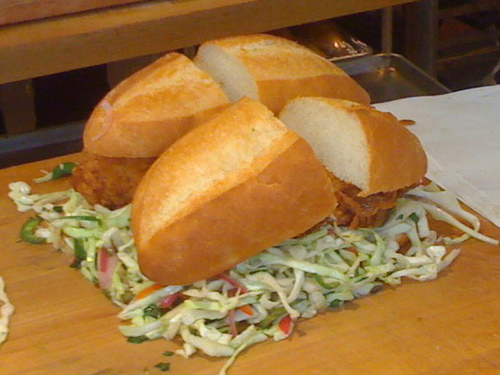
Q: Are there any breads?
A: Yes, there is a bread.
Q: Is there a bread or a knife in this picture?
A: Yes, there is a bread.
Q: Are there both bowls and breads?
A: No, there is a bread but no bowls.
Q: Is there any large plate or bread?
A: Yes, there is a large bread.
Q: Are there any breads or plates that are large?
A: Yes, the bread is large.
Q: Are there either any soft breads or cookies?
A: Yes, there is a soft bread.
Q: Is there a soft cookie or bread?
A: Yes, there is a soft bread.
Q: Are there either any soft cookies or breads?
A: Yes, there is a soft bread.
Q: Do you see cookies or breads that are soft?
A: Yes, the bread is soft.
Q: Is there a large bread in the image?
A: Yes, there is a large bread.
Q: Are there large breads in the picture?
A: Yes, there is a large bread.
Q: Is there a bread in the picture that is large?
A: Yes, there is a bread that is large.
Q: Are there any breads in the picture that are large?
A: Yes, there is a bread that is large.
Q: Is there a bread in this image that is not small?
A: Yes, there is a large bread.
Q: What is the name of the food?
A: The food is a bread.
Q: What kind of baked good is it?
A: The food is a bread.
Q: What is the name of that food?
A: This is a bread.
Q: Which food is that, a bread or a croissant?
A: This is a bread.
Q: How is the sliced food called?
A: The food is a bread.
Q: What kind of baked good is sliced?
A: The baked good is a bread.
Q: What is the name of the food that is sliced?
A: The food is a bread.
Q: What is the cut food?
A: The food is a bread.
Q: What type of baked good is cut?
A: The baked good is a bread.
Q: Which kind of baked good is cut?
A: The baked good is a bread.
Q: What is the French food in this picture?
A: The food is a bread.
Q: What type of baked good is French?
A: The baked good is a bread.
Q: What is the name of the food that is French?
A: The food is a bread.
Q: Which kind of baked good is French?
A: The baked good is a bread.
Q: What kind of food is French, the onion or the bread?
A: The bread is french.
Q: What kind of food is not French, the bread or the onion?
A: The onion is not french.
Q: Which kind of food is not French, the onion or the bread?
A: The onion is not french.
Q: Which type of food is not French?
A: The food is an onion.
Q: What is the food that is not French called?
A: The food is an onion.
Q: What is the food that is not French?
A: The food is an onion.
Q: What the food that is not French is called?
A: The food is an onion.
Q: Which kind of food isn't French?
A: The food is an onion.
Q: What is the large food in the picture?
A: The food is a bread.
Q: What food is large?
A: The food is a bread.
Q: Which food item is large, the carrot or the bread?
A: The bread is large.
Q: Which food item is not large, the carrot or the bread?
A: The carrot is not large.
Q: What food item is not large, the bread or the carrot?
A: The carrot is not large.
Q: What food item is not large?
A: The food item is a carrot.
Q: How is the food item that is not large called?
A: The food item is a carrot.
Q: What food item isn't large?
A: The food item is a carrot.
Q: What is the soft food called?
A: The food is a bread.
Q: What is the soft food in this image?
A: The food is a bread.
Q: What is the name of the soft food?
A: The food is a bread.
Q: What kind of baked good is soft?
A: The baked good is a bread.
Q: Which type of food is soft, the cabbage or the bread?
A: The bread is soft.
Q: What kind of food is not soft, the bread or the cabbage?
A: The cabbage is not soft.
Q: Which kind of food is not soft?
A: The food is a cabbage.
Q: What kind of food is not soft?
A: The food is a cabbage.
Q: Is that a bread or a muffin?
A: That is a bread.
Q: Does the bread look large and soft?
A: Yes, the bread is large and soft.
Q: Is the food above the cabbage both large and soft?
A: Yes, the bread is large and soft.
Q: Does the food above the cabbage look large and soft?
A: Yes, the bread is large and soft.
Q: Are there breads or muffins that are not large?
A: No, there is a bread but it is large.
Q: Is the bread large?
A: Yes, the bread is large.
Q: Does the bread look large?
A: Yes, the bread is large.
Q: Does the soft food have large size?
A: Yes, the bread is large.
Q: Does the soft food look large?
A: Yes, the bread is large.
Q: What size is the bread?
A: The bread is large.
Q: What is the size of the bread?
A: The bread is large.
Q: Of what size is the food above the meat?
A: The bread is large.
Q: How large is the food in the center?
A: The bread is large.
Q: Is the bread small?
A: No, the bread is large.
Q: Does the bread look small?
A: No, the bread is large.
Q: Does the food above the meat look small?
A: No, the bread is large.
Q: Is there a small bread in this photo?
A: No, there is a bread but it is large.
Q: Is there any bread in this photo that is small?
A: No, there is a bread but it is large.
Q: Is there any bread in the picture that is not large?
A: No, there is a bread but it is large.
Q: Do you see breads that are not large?
A: No, there is a bread but it is large.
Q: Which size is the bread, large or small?
A: The bread is large.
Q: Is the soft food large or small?
A: The bread is large.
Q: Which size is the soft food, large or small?
A: The bread is large.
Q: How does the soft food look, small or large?
A: The bread is large.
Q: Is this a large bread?
A: Yes, this is a large bread.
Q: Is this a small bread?
A: No, this is a large bread.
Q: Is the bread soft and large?
A: Yes, the bread is soft and large.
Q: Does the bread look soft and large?
A: Yes, the bread is soft and large.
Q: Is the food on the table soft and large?
A: Yes, the bread is soft and large.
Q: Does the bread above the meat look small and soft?
A: No, the bread is soft but large.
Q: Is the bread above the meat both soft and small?
A: No, the bread is soft but large.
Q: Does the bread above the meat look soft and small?
A: No, the bread is soft but large.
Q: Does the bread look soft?
A: Yes, the bread is soft.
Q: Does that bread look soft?
A: Yes, the bread is soft.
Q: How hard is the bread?
A: The bread is soft.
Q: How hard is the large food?
A: The bread is soft.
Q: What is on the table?
A: The bread is on the table.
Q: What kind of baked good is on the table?
A: The food is a bread.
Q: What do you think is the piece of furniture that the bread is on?
A: The piece of furniture is a table.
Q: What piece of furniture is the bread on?
A: The bread is on the table.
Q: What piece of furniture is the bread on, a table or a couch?
A: The bread is on a table.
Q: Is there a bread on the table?
A: Yes, there is a bread on the table.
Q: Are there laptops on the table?
A: No, there is a bread on the table.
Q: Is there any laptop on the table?
A: No, there is a bread on the table.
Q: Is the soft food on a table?
A: Yes, the bread is on a table.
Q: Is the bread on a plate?
A: No, the bread is on a table.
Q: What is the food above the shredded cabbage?
A: The food is a bread.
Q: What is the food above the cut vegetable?
A: The food is a bread.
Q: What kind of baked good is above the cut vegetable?
A: The food is a bread.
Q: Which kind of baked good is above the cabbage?
A: The food is a bread.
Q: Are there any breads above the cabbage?
A: Yes, there is a bread above the cabbage.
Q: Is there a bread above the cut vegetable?
A: Yes, there is a bread above the cabbage.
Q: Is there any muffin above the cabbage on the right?
A: No, there is a bread above the cabbage.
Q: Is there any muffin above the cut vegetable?
A: No, there is a bread above the cabbage.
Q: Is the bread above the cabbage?
A: Yes, the bread is above the cabbage.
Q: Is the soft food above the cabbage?
A: Yes, the bread is above the cabbage.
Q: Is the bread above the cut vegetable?
A: Yes, the bread is above the cabbage.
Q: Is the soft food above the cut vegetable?
A: Yes, the bread is above the cabbage.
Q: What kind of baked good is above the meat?
A: The food is a bread.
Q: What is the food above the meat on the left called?
A: The food is a bread.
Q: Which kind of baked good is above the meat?
A: The food is a bread.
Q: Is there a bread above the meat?
A: Yes, there is a bread above the meat.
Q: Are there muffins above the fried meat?
A: No, there is a bread above the meat.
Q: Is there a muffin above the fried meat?
A: No, there is a bread above the meat.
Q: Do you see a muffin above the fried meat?
A: No, there is a bread above the meat.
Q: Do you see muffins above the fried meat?
A: No, there is a bread above the meat.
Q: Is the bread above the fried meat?
A: Yes, the bread is above the meat.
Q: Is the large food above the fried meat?
A: Yes, the bread is above the meat.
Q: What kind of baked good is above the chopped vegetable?
A: The food is a bread.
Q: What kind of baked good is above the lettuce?
A: The food is a bread.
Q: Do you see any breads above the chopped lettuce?
A: Yes, there is a bread above the lettuce.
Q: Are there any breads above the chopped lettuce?
A: Yes, there is a bread above the lettuce.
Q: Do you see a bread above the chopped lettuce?
A: Yes, there is a bread above the lettuce.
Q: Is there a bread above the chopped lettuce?
A: Yes, there is a bread above the lettuce.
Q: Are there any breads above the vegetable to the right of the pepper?
A: Yes, there is a bread above the lettuce.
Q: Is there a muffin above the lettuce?
A: No, there is a bread above the lettuce.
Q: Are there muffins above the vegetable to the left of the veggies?
A: No, there is a bread above the lettuce.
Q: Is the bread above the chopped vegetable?
A: Yes, the bread is above the lettuce.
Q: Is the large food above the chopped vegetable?
A: Yes, the bread is above the lettuce.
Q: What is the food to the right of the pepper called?
A: The food is a bread.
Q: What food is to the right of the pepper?
A: The food is a bread.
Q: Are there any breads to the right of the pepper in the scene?
A: Yes, there is a bread to the right of the pepper.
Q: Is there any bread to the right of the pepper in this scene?
A: Yes, there is a bread to the right of the pepper.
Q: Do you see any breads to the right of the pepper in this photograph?
A: Yes, there is a bread to the right of the pepper.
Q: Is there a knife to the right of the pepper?
A: No, there is a bread to the right of the pepper.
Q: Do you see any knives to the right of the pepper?
A: No, there is a bread to the right of the pepper.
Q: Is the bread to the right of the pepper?
A: Yes, the bread is to the right of the pepper.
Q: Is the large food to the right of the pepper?
A: Yes, the bread is to the right of the pepper.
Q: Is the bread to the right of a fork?
A: No, the bread is to the right of the pepper.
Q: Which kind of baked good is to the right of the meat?
A: The food is a bread.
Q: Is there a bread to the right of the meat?
A: Yes, there is a bread to the right of the meat.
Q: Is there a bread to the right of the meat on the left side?
A: Yes, there is a bread to the right of the meat.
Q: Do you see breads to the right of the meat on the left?
A: Yes, there is a bread to the right of the meat.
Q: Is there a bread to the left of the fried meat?
A: No, the bread is to the right of the meat.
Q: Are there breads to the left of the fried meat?
A: No, the bread is to the right of the meat.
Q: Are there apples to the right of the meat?
A: No, there is a bread to the right of the meat.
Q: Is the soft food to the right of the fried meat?
A: Yes, the bread is to the right of the meat.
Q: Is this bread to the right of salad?
A: No, the bread is to the right of the meat.